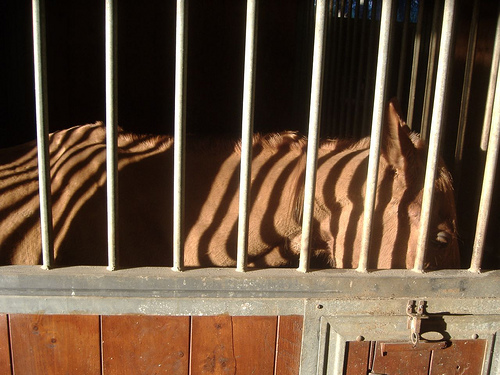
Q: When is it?
A: Daytime.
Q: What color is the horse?
A: Brown.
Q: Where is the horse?
A: Is a stable.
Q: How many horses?
A: 1.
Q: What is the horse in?
A: Cage.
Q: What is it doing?
A: Waiting.